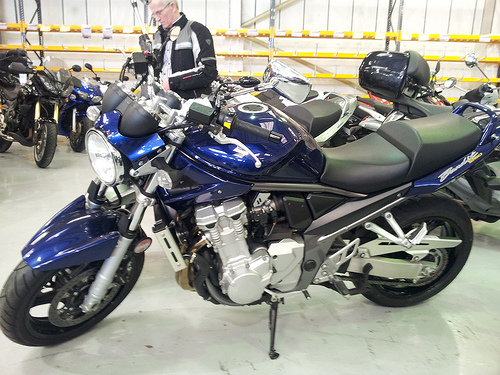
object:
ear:
[168, 0, 180, 13]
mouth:
[160, 19, 166, 26]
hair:
[150, 0, 179, 12]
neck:
[165, 12, 181, 29]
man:
[149, 0, 219, 102]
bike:
[0, 35, 500, 361]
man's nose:
[154, 16, 161, 24]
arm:
[169, 31, 217, 89]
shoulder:
[185, 19, 210, 34]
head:
[147, 0, 181, 30]